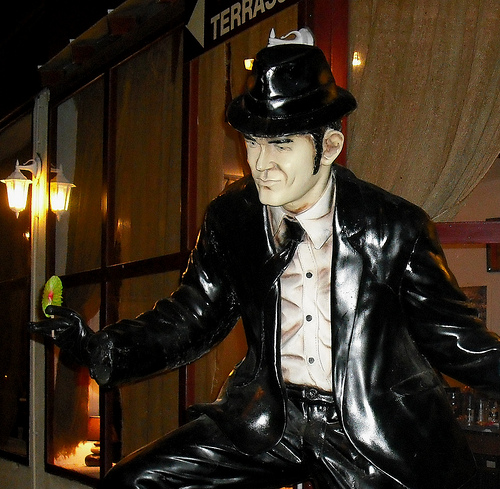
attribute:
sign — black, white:
[178, 0, 300, 69]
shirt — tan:
[268, 209, 343, 389]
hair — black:
[308, 131, 327, 174]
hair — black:
[255, 107, 364, 175]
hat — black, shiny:
[215, 36, 389, 136]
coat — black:
[88, 164, 497, 484]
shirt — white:
[265, 203, 340, 399]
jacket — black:
[104, 182, 497, 438]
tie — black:
[231, 214, 302, 314]